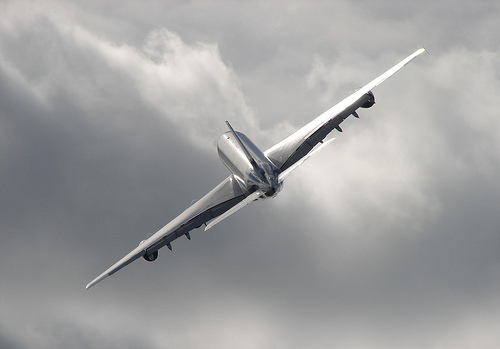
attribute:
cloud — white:
[84, 18, 261, 138]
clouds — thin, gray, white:
[1, 0, 498, 339]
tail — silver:
[248, 162, 283, 193]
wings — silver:
[78, 45, 423, 290]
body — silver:
[215, 128, 281, 200]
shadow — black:
[200, 155, 250, 185]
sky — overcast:
[11, 15, 328, 92]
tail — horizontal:
[225, 121, 268, 182]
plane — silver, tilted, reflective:
[82, 40, 425, 290]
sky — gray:
[0, 0, 498, 347]